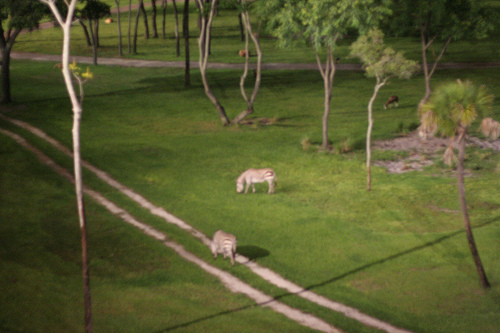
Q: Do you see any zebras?
A: Yes, there is a zebra.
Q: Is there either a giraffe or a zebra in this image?
A: Yes, there is a zebra.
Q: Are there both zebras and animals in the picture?
A: Yes, there are both a zebra and an animal.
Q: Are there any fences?
A: No, there are no fences.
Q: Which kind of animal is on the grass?
A: The animal is a zebra.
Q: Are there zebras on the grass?
A: Yes, there is a zebra on the grass.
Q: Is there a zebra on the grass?
A: Yes, there is a zebra on the grass.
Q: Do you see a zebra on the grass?
A: Yes, there is a zebra on the grass.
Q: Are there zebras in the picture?
A: Yes, there are zebras.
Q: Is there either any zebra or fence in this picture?
A: Yes, there are zebras.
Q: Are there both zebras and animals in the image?
A: Yes, there are both zebras and an animal.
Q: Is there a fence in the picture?
A: No, there are no fences.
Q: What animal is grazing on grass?
A: The zebras are grazing on grass.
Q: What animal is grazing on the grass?
A: The zebras are grazing on grass.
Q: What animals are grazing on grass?
A: The animals are zebras.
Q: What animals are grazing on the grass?
A: The animals are zebras.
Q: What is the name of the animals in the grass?
A: The animals are zebras.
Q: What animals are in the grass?
A: The animals are zebras.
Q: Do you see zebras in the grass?
A: Yes, there are zebras in the grass.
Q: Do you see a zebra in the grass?
A: Yes, there are zebras in the grass.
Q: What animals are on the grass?
A: The animals are zebras.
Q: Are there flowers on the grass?
A: No, there are zebras on the grass.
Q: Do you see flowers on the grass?
A: No, there are zebras on the grass.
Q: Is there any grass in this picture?
A: Yes, there is grass.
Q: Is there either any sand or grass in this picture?
A: Yes, there is grass.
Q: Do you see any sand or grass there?
A: Yes, there is grass.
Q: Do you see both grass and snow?
A: No, there is grass but no snow.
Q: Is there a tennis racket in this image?
A: No, there are no rackets.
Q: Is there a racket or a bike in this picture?
A: No, there are no rackets or bikes.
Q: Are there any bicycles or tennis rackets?
A: No, there are no tennis rackets or bicycles.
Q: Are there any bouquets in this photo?
A: No, there are no bouquets.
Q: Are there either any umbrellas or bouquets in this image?
A: No, there are no bouquets or umbrellas.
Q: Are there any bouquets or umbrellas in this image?
A: No, there are no bouquets or umbrellas.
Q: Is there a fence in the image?
A: No, there are no fences.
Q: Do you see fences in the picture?
A: No, there are no fences.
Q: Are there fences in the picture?
A: No, there are no fences.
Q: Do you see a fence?
A: No, there are no fences.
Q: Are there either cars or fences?
A: No, there are no fences or cars.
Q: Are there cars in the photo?
A: No, there are no cars.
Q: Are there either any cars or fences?
A: No, there are no cars or fences.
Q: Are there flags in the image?
A: No, there are no flags.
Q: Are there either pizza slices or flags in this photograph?
A: No, there are no flags or pizza slices.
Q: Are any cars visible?
A: No, there are no cars.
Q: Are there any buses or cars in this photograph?
A: No, there are no cars or buses.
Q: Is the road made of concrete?
A: Yes, the road is made of concrete.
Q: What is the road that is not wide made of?
A: The road is made of cement.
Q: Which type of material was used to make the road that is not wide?
A: The road is made of cement.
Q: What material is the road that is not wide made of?
A: The road is made of cement.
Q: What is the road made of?
A: The road is made of concrete.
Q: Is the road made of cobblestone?
A: No, the road is made of cement.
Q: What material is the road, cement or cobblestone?
A: The road is made of cement.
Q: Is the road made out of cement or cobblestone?
A: The road is made of cement.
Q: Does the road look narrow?
A: Yes, the road is narrow.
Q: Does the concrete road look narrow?
A: Yes, the road is narrow.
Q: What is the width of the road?
A: The road is narrow.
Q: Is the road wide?
A: No, the road is narrow.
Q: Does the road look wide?
A: No, the road is narrow.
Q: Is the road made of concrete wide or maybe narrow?
A: The road is narrow.